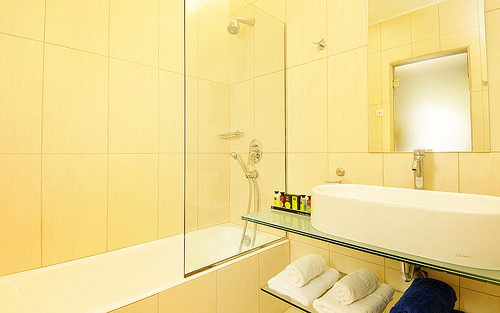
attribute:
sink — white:
[320, 170, 500, 263]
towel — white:
[286, 245, 317, 288]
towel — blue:
[401, 290, 448, 312]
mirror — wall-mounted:
[369, 58, 479, 157]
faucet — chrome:
[395, 131, 425, 188]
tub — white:
[0, 220, 285, 311]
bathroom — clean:
[5, 11, 500, 311]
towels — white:
[276, 258, 450, 312]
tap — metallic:
[400, 141, 431, 185]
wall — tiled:
[276, 21, 380, 187]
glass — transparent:
[172, 8, 291, 247]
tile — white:
[288, 20, 376, 189]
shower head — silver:
[226, 14, 254, 38]